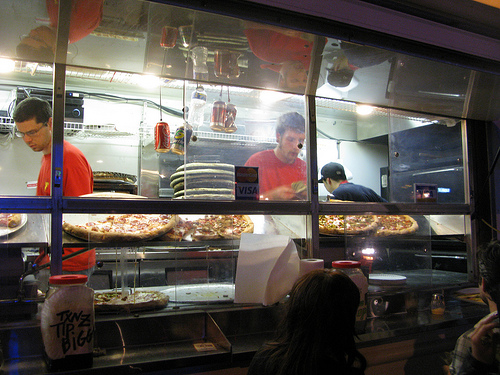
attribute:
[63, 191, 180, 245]
whole pizza — displayed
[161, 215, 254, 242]
whole pizza — displayed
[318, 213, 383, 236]
whole pizza — displayed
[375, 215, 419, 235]
whole pizza — displayed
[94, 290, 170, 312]
whole pizza — displayed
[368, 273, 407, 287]
plates — stacked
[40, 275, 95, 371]
tip jar — large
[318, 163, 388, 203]
chef — busy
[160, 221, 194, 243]
pizza — sliced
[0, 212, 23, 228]
pizza — sliced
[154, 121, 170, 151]
soda — coca cola, hanging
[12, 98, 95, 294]
man — busy, working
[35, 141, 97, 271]
shirt — red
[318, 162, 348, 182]
baseball hat — black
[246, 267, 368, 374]
person — waiting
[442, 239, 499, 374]
person — waiting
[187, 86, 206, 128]
water bottle — for sale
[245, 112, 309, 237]
worker — busy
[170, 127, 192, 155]
soda — hanging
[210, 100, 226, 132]
soda — hanging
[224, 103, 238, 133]
soda — hanging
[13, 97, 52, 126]
hair — brown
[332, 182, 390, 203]
shirt — black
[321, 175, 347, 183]
hair — black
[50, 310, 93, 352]
writing — black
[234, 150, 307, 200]
shirt — red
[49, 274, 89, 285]
lid — red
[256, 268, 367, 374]
hair — brown